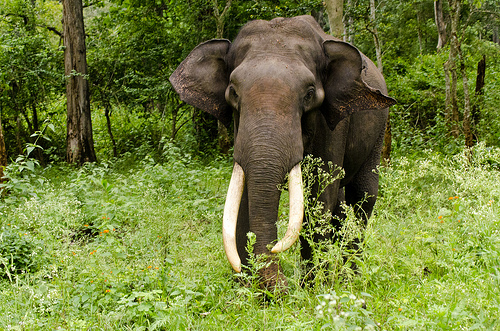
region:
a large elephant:
[158, 6, 386, 292]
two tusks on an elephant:
[208, 161, 307, 268]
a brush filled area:
[35, 175, 472, 317]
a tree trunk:
[41, 6, 109, 168]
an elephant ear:
[313, 33, 400, 133]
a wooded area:
[11, 1, 228, 152]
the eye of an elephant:
[293, 81, 326, 119]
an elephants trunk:
[236, 110, 298, 294]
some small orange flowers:
[432, 184, 465, 235]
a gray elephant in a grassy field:
[24, 5, 489, 315]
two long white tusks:
[202, 150, 317, 280]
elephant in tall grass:
[163, 10, 415, 295]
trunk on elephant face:
[238, 130, 293, 292]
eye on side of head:
[294, 73, 326, 113]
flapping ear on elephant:
[321, 33, 400, 130]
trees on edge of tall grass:
[28, 7, 178, 161]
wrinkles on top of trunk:
[244, 113, 286, 191]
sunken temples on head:
[290, 42, 329, 83]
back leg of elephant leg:
[335, 157, 387, 244]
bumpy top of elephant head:
[242, 12, 314, 38]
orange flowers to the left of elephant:
[68, 202, 191, 307]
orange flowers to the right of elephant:
[426, 170, 483, 235]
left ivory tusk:
[216, 140, 246, 292]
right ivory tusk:
[273, 152, 308, 264]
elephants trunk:
[241, 127, 307, 320]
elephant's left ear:
[157, 17, 239, 135]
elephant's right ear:
[320, 13, 408, 148]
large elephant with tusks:
[167, 35, 421, 305]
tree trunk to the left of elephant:
[3, 2, 120, 132]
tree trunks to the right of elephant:
[359, 10, 491, 166]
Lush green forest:
[4, 6, 168, 243]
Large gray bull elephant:
[155, 11, 415, 306]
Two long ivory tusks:
[216, 152, 311, 277]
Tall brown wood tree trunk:
[55, 2, 100, 172]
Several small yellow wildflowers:
[25, 207, 176, 318]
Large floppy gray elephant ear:
[157, 25, 232, 130]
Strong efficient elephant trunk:
[243, 132, 296, 325]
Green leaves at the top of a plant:
[20, 111, 58, 161]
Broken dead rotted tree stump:
[460, 50, 491, 148]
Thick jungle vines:
[94, 43, 169, 159]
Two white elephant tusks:
[219, 154, 310, 271]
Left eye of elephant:
[301, 79, 319, 106]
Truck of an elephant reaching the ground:
[234, 142, 299, 302]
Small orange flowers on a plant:
[73, 209, 113, 260]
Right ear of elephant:
[165, 35, 235, 117]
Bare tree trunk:
[48, 0, 102, 166]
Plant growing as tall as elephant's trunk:
[295, 156, 353, 286]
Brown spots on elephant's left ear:
[347, 80, 395, 112]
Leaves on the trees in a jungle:
[96, 9, 167, 90]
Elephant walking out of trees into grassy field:
[155, 11, 407, 317]